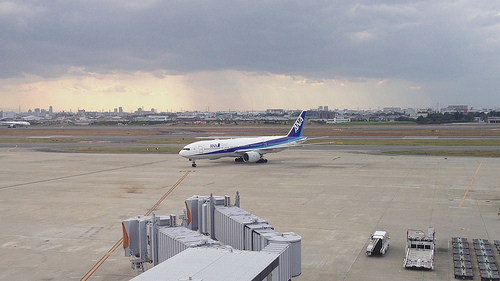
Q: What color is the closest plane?
A: White.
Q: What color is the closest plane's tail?
A: Blue.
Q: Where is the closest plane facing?
A: Left.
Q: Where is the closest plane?
A: On the ground.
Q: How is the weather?
A: Cloudy.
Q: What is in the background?
A: City.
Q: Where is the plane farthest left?
A: On the runway.